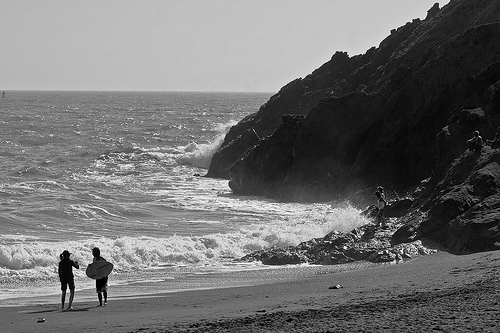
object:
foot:
[60, 306, 65, 311]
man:
[88, 246, 113, 308]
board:
[85, 261, 114, 280]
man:
[372, 191, 389, 228]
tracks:
[478, 253, 493, 260]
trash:
[35, 318, 50, 323]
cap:
[62, 250, 72, 255]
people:
[56, 249, 79, 312]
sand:
[495, 329, 500, 332]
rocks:
[365, 250, 404, 263]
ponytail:
[59, 253, 63, 261]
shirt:
[57, 259, 76, 283]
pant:
[60, 280, 75, 291]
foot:
[66, 306, 73, 311]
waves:
[176, 114, 241, 169]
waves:
[0, 194, 370, 281]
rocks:
[260, 251, 313, 266]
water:
[0, 89, 368, 304]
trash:
[328, 283, 344, 289]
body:
[87, 257, 111, 308]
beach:
[0, 248, 496, 333]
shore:
[0, 204, 396, 309]